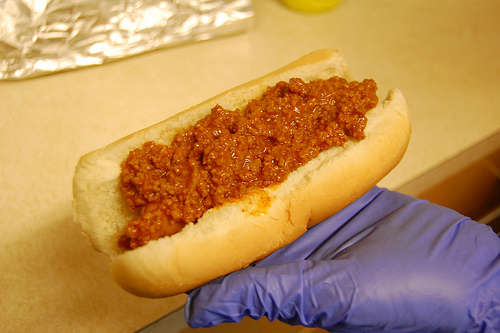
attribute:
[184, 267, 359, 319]
finger — tip